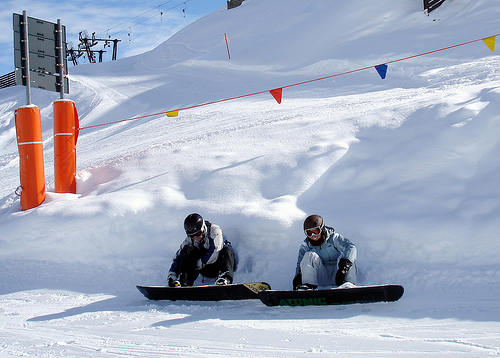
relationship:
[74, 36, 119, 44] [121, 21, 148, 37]
metal support hanging from wire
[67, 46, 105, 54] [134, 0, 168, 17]
metal support hanging from wire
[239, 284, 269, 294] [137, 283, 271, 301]
yellow front on snowboard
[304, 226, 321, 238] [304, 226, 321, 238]
eyewear on eyewear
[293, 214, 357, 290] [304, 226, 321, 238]
helmet man wearing eyewear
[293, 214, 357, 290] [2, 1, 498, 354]
helmet man resting on snow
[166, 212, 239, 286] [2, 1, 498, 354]
helmet man resting on snow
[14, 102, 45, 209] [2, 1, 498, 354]
object sticking out of snow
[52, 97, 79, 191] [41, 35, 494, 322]
object sticking out of snow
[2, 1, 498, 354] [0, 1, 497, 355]
snow on ground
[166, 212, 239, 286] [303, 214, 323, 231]
helmet man wearing helmet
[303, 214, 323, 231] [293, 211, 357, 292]
helmet on head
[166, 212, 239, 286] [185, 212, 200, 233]
helmet man wearing helmet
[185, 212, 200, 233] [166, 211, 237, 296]
helmet on head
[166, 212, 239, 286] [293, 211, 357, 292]
helmet man has head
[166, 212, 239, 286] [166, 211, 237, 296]
helmet man has head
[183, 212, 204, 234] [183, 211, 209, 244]
helmet on head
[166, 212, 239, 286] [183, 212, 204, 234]
helmet man wearing helmet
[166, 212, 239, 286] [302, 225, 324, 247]
helmet man wearing eyewear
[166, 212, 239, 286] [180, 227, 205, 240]
helmet man wearing eyewear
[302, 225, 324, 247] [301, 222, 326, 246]
eyewear on face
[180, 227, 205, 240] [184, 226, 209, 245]
eyewear on face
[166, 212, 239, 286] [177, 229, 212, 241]
helmet man wearing eyewear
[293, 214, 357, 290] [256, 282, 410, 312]
helmet man on snowboard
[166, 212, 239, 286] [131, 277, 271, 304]
helmet man on snowboard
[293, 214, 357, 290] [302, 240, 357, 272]
helmet man wearing jacket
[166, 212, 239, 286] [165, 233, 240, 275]
helmet man wearing jacket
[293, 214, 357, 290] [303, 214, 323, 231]
helmet man wearing helmet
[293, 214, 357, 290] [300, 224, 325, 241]
helmet man wearing goggles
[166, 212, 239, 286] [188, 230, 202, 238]
helmet man wearing eyewear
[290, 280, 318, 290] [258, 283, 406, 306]
foot on snowboard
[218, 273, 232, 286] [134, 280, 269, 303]
foot on snowboard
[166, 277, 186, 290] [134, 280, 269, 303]
foot on snowboard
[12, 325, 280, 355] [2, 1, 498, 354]
tracks on snow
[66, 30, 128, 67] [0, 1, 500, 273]
ski lift over hill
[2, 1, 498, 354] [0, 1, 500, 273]
snow on hill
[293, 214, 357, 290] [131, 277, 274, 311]
helmet man adjusting snowboard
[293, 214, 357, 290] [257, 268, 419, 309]
helmet man adjusting snowboard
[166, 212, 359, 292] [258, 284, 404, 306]
couple adjusting snowboard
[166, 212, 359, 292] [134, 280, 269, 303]
couple adjusting snowboard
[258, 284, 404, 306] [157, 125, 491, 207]
snowboard in snow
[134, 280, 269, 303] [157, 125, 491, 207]
snowboard in snow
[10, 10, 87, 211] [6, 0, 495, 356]
sign in ski area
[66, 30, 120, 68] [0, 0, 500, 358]
ski lift in ski area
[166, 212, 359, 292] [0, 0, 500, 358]
couple on ski area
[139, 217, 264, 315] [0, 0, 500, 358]
couple on ski area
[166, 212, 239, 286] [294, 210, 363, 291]
helmet man dressed in snowboarding gear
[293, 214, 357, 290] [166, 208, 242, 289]
helmet man dressed in snowboarding gear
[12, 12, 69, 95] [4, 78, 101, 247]
sign attached to supports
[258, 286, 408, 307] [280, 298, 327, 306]
snowboard with lettering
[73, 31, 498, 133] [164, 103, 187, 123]
rope with flag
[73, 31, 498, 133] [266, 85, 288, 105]
rope with flag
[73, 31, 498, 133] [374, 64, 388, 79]
rope with blue pennant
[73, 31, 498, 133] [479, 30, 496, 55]
rope with flag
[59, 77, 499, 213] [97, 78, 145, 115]
hill with tracks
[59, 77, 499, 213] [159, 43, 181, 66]
hill with tracks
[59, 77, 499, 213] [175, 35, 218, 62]
hill with tracks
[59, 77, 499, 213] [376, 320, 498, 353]
hill with tracks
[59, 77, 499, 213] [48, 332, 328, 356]
hill with tracks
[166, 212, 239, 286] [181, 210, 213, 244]
helmet man with helmet